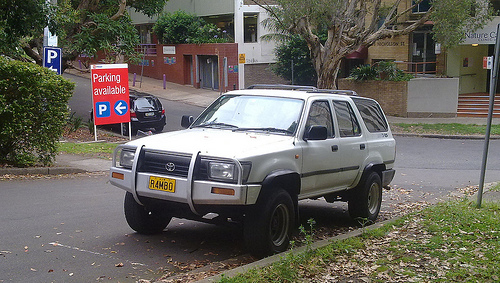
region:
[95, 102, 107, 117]
large white letter P on blue square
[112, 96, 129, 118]
large left pointing white arrow on blue circle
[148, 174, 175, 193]
yellow license plate reading "RAMBO"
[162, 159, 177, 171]
small vehicle emblem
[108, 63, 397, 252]
white all terrain vehicle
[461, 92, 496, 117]
red brick steps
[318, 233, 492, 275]
dead leaves on short grass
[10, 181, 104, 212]
smooth gray paved road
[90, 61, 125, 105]
large white text on red stating "Parking Available"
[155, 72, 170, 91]
short red metal pole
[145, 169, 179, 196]
yellow and black license plate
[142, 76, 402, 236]
white SUV parked on side of road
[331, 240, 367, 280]
dried leaves on the grass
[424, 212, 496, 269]
patches of green grass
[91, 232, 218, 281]
dried brown leaves on cement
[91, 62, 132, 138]
red sign with white text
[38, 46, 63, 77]
blue and white parking sign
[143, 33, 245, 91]
brown building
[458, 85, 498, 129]
brown stairs of building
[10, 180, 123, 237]
black cement road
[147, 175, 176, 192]
the yellow license plate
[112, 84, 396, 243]
the white SUV parked on the street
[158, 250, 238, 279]
the leaves on the ground in front of the car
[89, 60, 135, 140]
the parking available sign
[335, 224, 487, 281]
the brown leaves next to the white SUV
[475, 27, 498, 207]
the pole near the suv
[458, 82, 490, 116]
the stairs on the building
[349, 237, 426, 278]
the pile of leaves near the white suv drivers door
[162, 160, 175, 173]
the logo on the white SUV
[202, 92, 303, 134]
the windshield on the white SUV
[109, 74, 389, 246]
a white Toyota truck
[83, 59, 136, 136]
a red and blue parking sign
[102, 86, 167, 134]
a parked black SUV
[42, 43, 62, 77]
a blue parking sign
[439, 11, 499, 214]
a white street sign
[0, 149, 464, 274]
a paved city street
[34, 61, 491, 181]
a paved city street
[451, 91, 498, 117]
a red staircase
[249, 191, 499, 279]
green grass with autumn leaves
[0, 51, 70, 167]
a trimmed green bush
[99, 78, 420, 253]
the SUV is white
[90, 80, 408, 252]
the SUV is parked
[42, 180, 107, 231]
the road is black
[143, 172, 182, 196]
the plate is yellow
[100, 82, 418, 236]
the SUV has headlights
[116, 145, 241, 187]
the headlights are off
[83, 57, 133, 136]
the sign is red white and blue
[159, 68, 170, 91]
the pole is purple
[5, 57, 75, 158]
the hedge has been trimmed